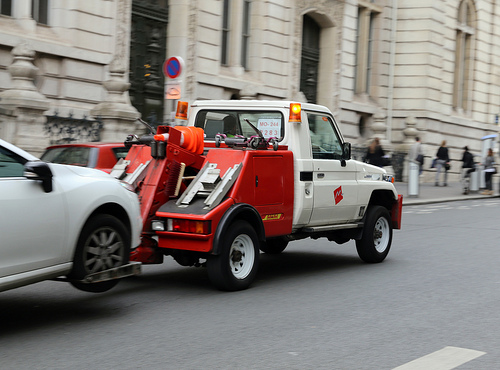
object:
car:
[98, 98, 404, 292]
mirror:
[21, 159, 54, 195]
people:
[426, 139, 453, 187]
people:
[406, 136, 426, 178]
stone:
[341, 39, 358, 54]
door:
[300, 106, 358, 227]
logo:
[331, 184, 343, 206]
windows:
[220, 26, 229, 67]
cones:
[150, 125, 205, 157]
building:
[0, 0, 398, 189]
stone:
[257, 28, 293, 49]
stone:
[396, 18, 448, 36]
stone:
[390, 97, 443, 114]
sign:
[160, 55, 183, 80]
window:
[193, 107, 242, 139]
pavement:
[390, 179, 499, 206]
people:
[476, 147, 498, 173]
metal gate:
[40, 105, 104, 149]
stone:
[193, 37, 223, 60]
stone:
[393, 64, 447, 82]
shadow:
[0, 251, 363, 338]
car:
[0, 136, 146, 296]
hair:
[365, 135, 380, 145]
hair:
[437, 139, 445, 149]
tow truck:
[32, 98, 404, 293]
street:
[0, 196, 499, 369]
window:
[234, 108, 284, 141]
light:
[286, 101, 302, 123]